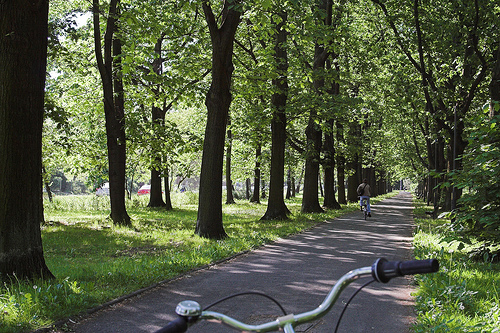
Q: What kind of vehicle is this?
A: Bicycle.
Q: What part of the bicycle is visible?
A: Handlebars.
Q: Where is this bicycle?
A: Bike path.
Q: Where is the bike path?
A: Park.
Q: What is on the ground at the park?
A: Grass.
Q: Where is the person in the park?
A: On the bike path.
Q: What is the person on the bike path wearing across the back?
A: Backpack.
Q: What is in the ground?
A: Tree.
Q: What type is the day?
A: Sunny.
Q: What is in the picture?
A: Bike.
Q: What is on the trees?
A: Leaves.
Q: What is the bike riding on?
A: Road.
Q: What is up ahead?
A: Human.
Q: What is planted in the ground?
A: Grass.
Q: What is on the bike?
A: Bell.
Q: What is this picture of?
A: Handle bars.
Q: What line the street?
A: Trees.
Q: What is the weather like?
A: Sunny.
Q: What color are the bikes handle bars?
A: Silver.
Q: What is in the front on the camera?
A: Bike handles.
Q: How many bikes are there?
A: One.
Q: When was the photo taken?
A: Daytime.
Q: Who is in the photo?
A: A man.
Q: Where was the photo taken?
A: On the street.